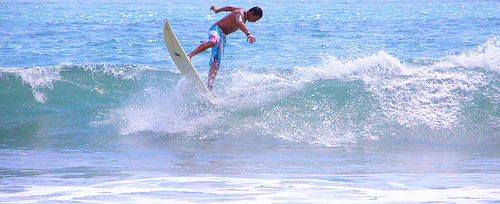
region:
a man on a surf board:
[147, 9, 299, 116]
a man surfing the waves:
[133, 1, 312, 135]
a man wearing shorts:
[192, 7, 285, 79]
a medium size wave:
[87, 19, 434, 131]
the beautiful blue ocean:
[264, 1, 388, 151]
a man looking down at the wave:
[190, 4, 289, 92]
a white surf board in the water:
[159, 9, 221, 134]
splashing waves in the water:
[237, 17, 457, 153]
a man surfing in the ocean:
[142, 2, 352, 99]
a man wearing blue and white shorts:
[197, 11, 269, 70]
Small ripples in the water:
[436, 154, 451, 187]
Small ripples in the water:
[398, 60, 470, 130]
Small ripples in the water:
[314, 112, 383, 172]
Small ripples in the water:
[233, 119, 300, 176]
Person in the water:
[150, 1, 300, 104]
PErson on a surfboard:
[147, 2, 294, 128]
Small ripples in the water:
[112, 151, 180, 201]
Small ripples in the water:
[28, 62, 98, 110]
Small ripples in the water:
[68, 9, 110, 49]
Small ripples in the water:
[283, 21, 342, 72]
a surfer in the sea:
[10, 6, 455, 173]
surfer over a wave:
[7, 1, 480, 144]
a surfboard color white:
[153, 11, 215, 115]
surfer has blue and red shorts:
[153, 2, 269, 103]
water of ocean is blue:
[1, 6, 168, 55]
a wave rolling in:
[1, 53, 493, 151]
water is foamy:
[3, 125, 499, 202]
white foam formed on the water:
[9, 139, 490, 201]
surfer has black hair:
[181, 4, 272, 92]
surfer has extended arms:
[202, 5, 274, 55]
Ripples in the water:
[433, 108, 458, 167]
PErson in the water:
[150, 6, 262, 120]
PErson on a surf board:
[145, 0, 296, 129]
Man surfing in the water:
[145, 4, 284, 124]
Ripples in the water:
[9, 56, 86, 123]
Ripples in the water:
[66, 44, 124, 101]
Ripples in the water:
[105, 43, 180, 113]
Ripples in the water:
[231, 58, 301, 100]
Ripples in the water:
[130, 160, 252, 195]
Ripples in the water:
[263, 164, 366, 200]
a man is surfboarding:
[122, 2, 335, 135]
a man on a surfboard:
[144, 8, 307, 150]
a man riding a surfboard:
[140, 9, 340, 136]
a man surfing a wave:
[127, 4, 297, 124]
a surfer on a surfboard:
[146, 8, 325, 140]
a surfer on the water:
[133, 15, 283, 117]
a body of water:
[36, 19, 475, 201]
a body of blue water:
[32, 22, 448, 203]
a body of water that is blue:
[29, 7, 441, 203]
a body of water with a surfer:
[64, 11, 382, 185]